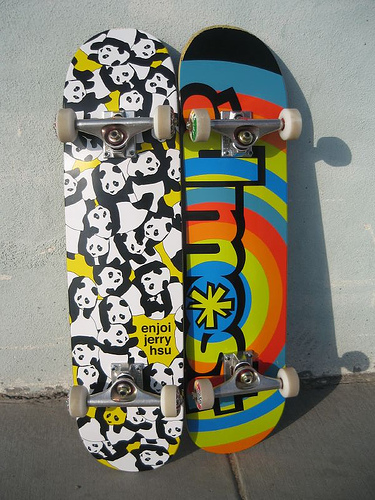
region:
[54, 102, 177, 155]
two wheels on wheel holder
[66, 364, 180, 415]
two wheels on wheel holder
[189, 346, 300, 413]
two wheels on wheel holder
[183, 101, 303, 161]
two wheels on wheel holder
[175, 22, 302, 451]
rainbow colored skateboard plate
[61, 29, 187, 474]
skateboard plate with panda drawings decoration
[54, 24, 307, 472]
two skateboards leaning against white wall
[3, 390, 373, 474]
skateboards leaning on concrete ground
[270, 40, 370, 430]
shadow of skateboard casting on wall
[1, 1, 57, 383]
concrete wall painted white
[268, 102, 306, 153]
wheel on a skate board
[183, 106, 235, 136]
wheel on a skate board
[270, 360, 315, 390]
wheel on a skate board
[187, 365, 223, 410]
wheel on a skate board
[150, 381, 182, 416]
wheel on a skate board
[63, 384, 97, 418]
wheel on a skate board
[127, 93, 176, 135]
wheel on a skate board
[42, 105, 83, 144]
wheel on a skate board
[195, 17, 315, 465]
skate board on a wall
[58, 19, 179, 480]
skate board on a wall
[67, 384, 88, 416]
the white wheel of the skateboard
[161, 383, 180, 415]
the white wheel of the skateboard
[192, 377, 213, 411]
the white wheel of the skateboard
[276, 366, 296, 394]
the white wheel of the skateboard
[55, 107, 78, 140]
the white wheel of the skateboard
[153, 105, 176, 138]
the white wheel of the skateboard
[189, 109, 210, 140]
the white wheel of the skateboard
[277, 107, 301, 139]
the white wheel of the skateboard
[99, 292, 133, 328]
the panda on the skateboard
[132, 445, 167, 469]
the panda on the skateboard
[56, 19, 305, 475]
two skateboards side by side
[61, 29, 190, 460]
panda bear print on bottom of the skateboard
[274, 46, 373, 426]
shadow of the skateboard on the wall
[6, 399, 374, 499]
sidewalk the skateboards are propped on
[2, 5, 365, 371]
wall the skateboards are leaning against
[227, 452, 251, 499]
line in the sidewalk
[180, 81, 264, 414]
lettering outlined in black on bottom skateboard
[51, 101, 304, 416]
white wheels on the skateboards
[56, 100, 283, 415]
axles on the skateboards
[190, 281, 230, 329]
green asterick on the skateboard